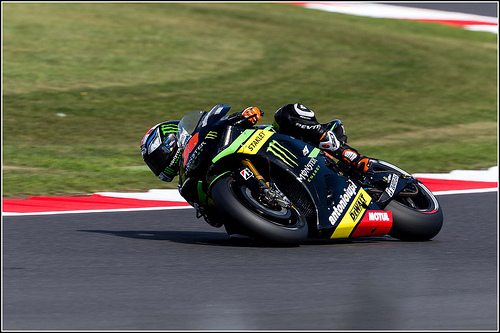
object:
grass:
[3, 1, 498, 197]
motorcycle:
[169, 104, 446, 246]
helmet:
[140, 122, 185, 182]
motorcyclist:
[137, 104, 418, 228]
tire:
[211, 175, 309, 243]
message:
[249, 131, 266, 152]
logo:
[265, 139, 299, 168]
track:
[2, 0, 500, 333]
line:
[1, 205, 194, 234]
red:
[4, 194, 192, 212]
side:
[5, 187, 188, 213]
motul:
[368, 212, 389, 221]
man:
[138, 104, 418, 204]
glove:
[237, 106, 261, 125]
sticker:
[212, 128, 254, 163]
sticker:
[236, 131, 276, 155]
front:
[180, 129, 311, 252]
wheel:
[373, 159, 443, 241]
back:
[346, 108, 444, 238]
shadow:
[76, 226, 248, 251]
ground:
[0, 0, 500, 333]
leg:
[272, 101, 377, 188]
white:
[97, 188, 187, 202]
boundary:
[3, 176, 144, 223]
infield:
[0, 0, 500, 196]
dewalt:
[351, 193, 368, 220]